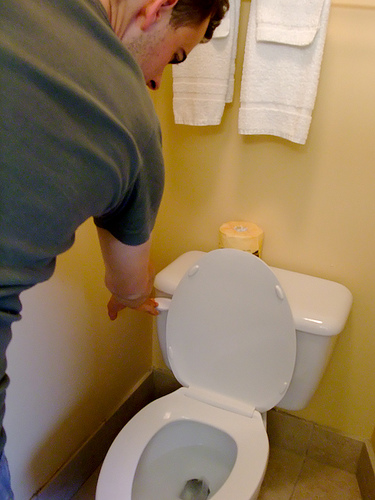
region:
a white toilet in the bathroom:
[69, 245, 356, 495]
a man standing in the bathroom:
[4, 1, 232, 498]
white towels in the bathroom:
[165, 2, 336, 149]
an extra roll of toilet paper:
[220, 221, 261, 255]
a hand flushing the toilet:
[105, 285, 170, 325]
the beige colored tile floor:
[272, 414, 374, 497]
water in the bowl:
[145, 446, 224, 499]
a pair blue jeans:
[0, 456, 19, 498]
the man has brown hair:
[171, 1, 228, 41]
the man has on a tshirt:
[0, 2, 171, 466]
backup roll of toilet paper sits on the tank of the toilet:
[218, 219, 263, 258]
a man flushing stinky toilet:
[0, 0, 229, 499]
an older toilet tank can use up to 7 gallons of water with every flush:
[153, 249, 351, 411]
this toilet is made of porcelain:
[94, 248, 351, 498]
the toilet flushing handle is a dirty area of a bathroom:
[148, 296, 171, 309]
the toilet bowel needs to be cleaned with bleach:
[130, 418, 237, 498]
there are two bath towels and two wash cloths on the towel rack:
[237, 0, 330, 145]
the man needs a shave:
[100, 0, 228, 91]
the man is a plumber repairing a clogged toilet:
[0, 0, 229, 498]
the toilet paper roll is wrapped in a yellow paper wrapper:
[218, 220, 263, 261]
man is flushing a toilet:
[106, 273, 170, 321]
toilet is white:
[81, 247, 354, 498]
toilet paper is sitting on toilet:
[215, 217, 267, 266]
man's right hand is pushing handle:
[100, 282, 161, 321]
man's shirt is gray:
[1, 51, 163, 454]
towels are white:
[235, 1, 332, 148]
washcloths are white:
[253, 0, 330, 48]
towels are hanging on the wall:
[164, 1, 333, 146]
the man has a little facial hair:
[124, 26, 180, 73]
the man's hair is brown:
[167, 0, 231, 47]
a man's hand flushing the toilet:
[112, 291, 174, 314]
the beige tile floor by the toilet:
[267, 409, 373, 499]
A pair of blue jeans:
[0, 452, 24, 499]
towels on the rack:
[151, 1, 323, 141]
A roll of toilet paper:
[216, 216, 269, 263]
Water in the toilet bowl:
[145, 451, 219, 497]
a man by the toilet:
[6, 5, 228, 385]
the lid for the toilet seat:
[167, 251, 285, 422]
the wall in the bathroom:
[19, 322, 140, 424]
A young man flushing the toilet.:
[2, 0, 374, 498]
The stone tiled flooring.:
[275, 428, 374, 498]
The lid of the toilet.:
[164, 247, 291, 403]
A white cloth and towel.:
[233, 2, 356, 148]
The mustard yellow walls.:
[324, 376, 371, 427]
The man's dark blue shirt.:
[32, 44, 128, 157]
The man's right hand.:
[105, 282, 165, 318]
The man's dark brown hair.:
[170, 1, 229, 38]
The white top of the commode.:
[296, 275, 346, 329]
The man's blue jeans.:
[0, 435, 17, 499]